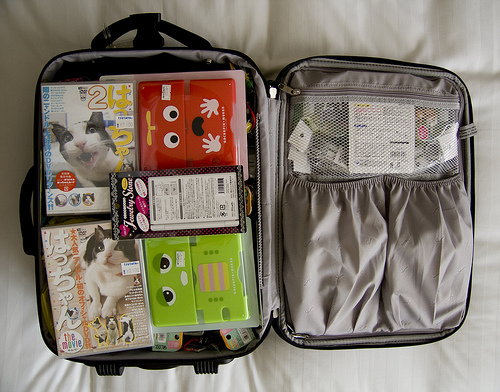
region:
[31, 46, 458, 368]
an open black suitcase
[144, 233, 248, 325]
green square character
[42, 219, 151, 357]
orange DVD with a cat on the front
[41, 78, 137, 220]
DVD case with a cat and the number 2 on it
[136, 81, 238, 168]
red, surprised looking toy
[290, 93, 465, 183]
mesh pocket on suitcase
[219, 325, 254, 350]
green and orange tag with a hole in it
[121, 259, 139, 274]
price sticker on orange cat DVD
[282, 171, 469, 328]
brown pockets on the suitcase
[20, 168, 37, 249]
handle of the suitcase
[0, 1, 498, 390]
white sheet under suitcase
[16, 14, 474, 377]
small open suitcase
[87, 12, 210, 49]
black handle on top of suitcase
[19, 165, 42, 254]
black handle on side of suitcase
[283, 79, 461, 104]
zipper is gray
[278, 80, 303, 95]
silver metal zipper pull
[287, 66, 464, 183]
mesh compartment inside suitcase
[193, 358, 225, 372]
two wheels on bottom of suitcase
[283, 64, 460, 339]
lining of suitcase is gray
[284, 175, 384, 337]
two pockets inside suitcase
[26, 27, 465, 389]
this luggage is stuffed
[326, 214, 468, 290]
the lining is grey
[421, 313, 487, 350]
the sheets are white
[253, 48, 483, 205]
mesh net is full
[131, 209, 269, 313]
this case is green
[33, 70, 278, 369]
the dvds are about cats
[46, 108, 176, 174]
a black and white cat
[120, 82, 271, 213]
this case is red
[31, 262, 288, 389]
the luggage has wheels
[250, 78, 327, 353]
the luggage has zippers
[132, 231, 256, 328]
green disc holder with silly face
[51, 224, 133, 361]
cat on magazine cover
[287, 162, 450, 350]
gray pouch for holding things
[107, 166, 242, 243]
cards in a pack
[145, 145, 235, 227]
black and white cards in a pack.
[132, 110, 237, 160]
Red silly face disk holder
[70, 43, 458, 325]
gray zipper pack that holds items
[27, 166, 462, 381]
open gray zipper pack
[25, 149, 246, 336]
assorted objects bundled together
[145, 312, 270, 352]
small items that are pink and green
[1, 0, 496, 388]
The bag is on the bed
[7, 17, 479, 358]
the bag is black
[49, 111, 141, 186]
the cat is gray and white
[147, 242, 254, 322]
a face is on the package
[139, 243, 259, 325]
the package is green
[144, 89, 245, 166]
the package is red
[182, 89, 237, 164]
the package has white hands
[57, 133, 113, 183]
the cat's mouth is open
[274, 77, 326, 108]
the bag has a zipper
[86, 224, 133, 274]
the cat's mouth is closed